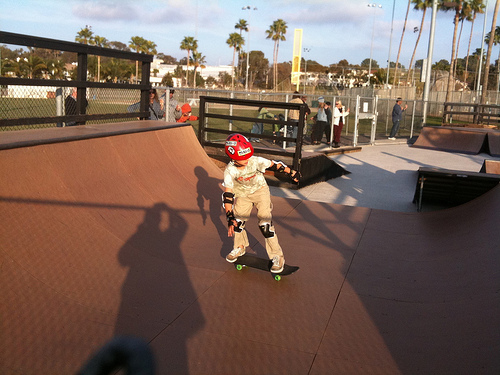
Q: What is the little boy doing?
A: Skateboarding.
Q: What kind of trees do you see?
A: Palm trees.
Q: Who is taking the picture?
A: A photographer.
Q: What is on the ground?
A: Shadows.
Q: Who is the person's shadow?
A: Photographer.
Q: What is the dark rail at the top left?
A: Fence.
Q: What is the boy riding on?
A: Skateboard.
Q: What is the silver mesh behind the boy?
A: Metal fence.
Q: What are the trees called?
A: Palm trees.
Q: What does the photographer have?
A: Camera.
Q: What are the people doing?
A: Watching.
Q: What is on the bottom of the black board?
A: Wheels.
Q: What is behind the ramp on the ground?
A: Grass.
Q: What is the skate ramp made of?
A: Wood.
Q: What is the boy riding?
A: A skateboard.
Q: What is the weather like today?
A: Partly cloudy.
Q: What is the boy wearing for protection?
A: Elbow and knee pads.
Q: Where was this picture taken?
A: At a park.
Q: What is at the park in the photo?
A: A skateboarding area.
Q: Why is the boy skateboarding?
A: To enjoy the sport.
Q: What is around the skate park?
A: A fence.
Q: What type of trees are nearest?
A: Palm trees.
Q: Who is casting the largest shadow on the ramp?
A: The person taking the photo.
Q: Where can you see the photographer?
A: On the ramp.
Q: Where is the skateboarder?
A: On the ramp.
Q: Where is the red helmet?
A: On skateboarder.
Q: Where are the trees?
A: Beyond the fence.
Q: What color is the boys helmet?
A: Red.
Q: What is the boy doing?
A: Skateboarding.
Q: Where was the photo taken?
A: A park.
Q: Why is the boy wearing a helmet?
A: To protect his head.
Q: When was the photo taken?
A: Day time.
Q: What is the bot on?
A: A skateboard.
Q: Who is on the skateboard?
A: A boy.